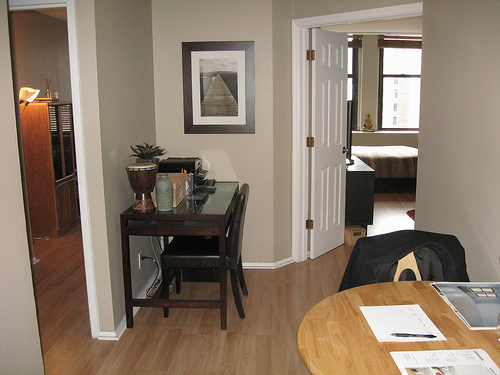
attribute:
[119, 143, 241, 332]
desk — brown, wooden, dark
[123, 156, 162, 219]
bongo drum — brown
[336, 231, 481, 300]
jacket — black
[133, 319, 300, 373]
floor — wooden, brown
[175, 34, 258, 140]
picture — brown, framed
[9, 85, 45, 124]
lamp — on, small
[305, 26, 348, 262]
door — open, white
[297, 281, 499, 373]
table — wooden, round, light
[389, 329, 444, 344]
pen — black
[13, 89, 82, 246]
cabinet — wooden, brown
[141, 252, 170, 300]
cord — black, plugged in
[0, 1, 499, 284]
walls — beige, painted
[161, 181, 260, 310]
chair — brown, dark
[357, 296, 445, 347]
paper — white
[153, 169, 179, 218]
vase — small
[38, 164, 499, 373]
floors — wooden, light brown